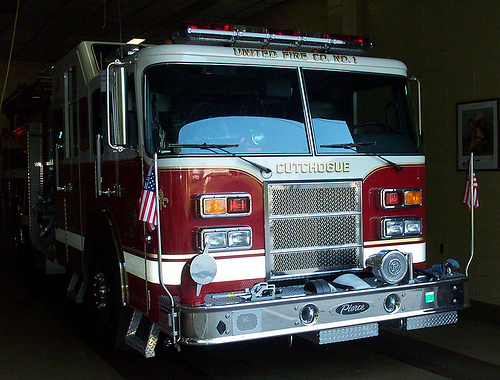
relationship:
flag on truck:
[139, 162, 162, 226] [1, 26, 472, 345]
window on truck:
[145, 63, 421, 157] [1, 26, 472, 345]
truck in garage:
[1, 26, 472, 345] [0, 1, 499, 379]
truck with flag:
[1, 26, 472, 345] [461, 151, 479, 211]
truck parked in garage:
[1, 26, 472, 345] [0, 1, 499, 379]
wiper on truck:
[168, 140, 268, 173] [1, 26, 472, 345]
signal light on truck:
[202, 196, 225, 212] [1, 26, 472, 345]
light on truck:
[227, 196, 250, 213] [1, 26, 472, 345]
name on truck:
[233, 45, 358, 66] [1, 26, 472, 345]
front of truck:
[136, 23, 469, 339] [1, 26, 472, 345]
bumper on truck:
[177, 271, 474, 343] [1, 26, 472, 345]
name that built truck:
[233, 45, 358, 66] [1, 26, 472, 345]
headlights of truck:
[197, 191, 422, 245] [1, 26, 472, 345]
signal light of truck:
[202, 196, 225, 212] [1, 26, 472, 345]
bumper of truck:
[177, 271, 474, 343] [1, 26, 472, 345]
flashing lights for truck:
[183, 17, 379, 57] [1, 26, 472, 345]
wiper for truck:
[168, 140, 268, 173] [1, 26, 472, 345]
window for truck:
[145, 63, 421, 157] [1, 26, 472, 345]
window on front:
[145, 63, 421, 157] [136, 23, 469, 339]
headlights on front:
[197, 191, 422, 245] [136, 23, 469, 339]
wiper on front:
[168, 140, 268, 173] [136, 23, 469, 339]